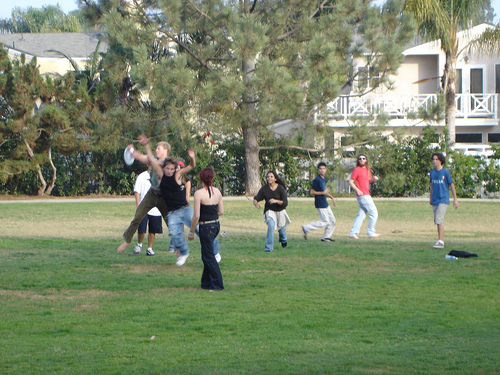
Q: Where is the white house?
A: Behind the people.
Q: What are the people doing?
A: Playing frisbee.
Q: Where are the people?
A: On the grass.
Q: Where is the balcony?
A: On the house.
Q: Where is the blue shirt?
A: On the man.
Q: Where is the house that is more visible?
A: In the rear on the right.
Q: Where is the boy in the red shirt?
A: The second from the right.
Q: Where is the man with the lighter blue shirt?
A: On the far right.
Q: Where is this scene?
A: A large field.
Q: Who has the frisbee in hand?
A: The man in the brown pants?.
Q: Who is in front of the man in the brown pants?
A: The man in the black shirt.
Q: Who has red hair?
A: The woman closest to the camera.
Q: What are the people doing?
A: Playing frisbee.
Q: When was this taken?
A: During the day.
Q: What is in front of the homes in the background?
A: Trees and bushes.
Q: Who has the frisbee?
A: The man with the blonde hair.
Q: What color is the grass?
A: Green.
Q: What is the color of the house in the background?
A: White.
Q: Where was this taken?
A: In a field.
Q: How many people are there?
A: Nine.